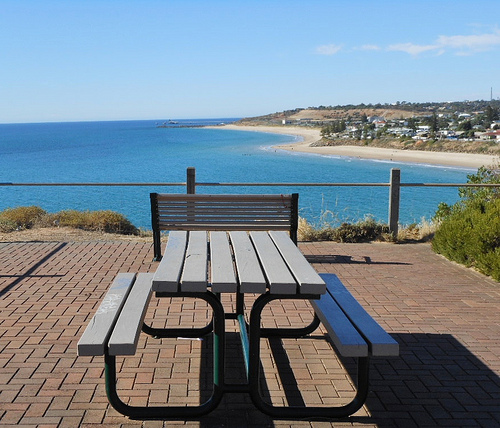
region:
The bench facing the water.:
[142, 190, 302, 244]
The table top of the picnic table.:
[157, 225, 321, 287]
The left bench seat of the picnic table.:
[87, 273, 141, 355]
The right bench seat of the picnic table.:
[302, 272, 397, 360]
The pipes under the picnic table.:
[109, 294, 365, 416]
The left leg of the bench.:
[147, 227, 164, 260]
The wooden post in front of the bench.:
[183, 158, 402, 238]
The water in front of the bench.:
[12, 127, 466, 234]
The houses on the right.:
[322, 115, 499, 142]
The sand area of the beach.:
[231, 122, 498, 177]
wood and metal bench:
[148, 193, 298, 260]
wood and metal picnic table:
[78, 231, 399, 426]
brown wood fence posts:
[1, 168, 498, 240]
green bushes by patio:
[430, 199, 499, 283]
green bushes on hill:
[1, 207, 144, 239]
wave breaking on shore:
[254, 145, 490, 176]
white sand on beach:
[305, 145, 496, 165]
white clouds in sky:
[313, 34, 497, 62]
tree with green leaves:
[453, 168, 496, 200]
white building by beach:
[280, 117, 288, 125]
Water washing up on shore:
[276, 114, 308, 163]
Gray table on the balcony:
[154, 218, 324, 310]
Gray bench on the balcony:
[315, 260, 403, 369]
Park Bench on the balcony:
[142, 185, 312, 247]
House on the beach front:
[365, 115, 470, 142]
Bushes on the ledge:
[37, 210, 137, 234]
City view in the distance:
[411, 96, 495, 160]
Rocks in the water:
[158, 108, 203, 139]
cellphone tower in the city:
[487, 88, 495, 103]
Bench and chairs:
[65, 214, 404, 394]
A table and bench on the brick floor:
[106, 225, 396, 379]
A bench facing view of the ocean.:
[146, 175, 298, 242]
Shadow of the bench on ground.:
[346, 310, 477, 416]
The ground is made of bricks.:
[387, 255, 469, 406]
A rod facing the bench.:
[51, 165, 418, 195]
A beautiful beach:
[43, 115, 222, 184]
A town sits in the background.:
[308, 88, 485, 153]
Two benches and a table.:
[93, 248, 393, 380]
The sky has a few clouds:
[98, 19, 471, 102]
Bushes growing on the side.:
[441, 176, 496, 256]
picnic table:
[77, 229, 398, 420]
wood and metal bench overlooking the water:
[148, 189, 300, 258]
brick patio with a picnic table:
[2, 242, 497, 425]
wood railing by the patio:
[2, 173, 498, 240]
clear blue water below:
[0, 123, 478, 225]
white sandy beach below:
[215, 122, 498, 172]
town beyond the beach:
[320, 120, 498, 140]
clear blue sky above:
[2, 5, 499, 106]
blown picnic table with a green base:
[79, 221, 396, 421]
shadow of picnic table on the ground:
[207, 333, 498, 427]